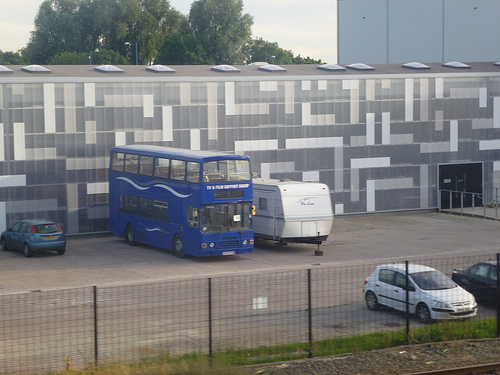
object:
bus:
[106, 143, 254, 261]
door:
[433, 161, 489, 211]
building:
[0, 2, 498, 238]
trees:
[182, 0, 254, 68]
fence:
[0, 250, 499, 370]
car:
[0, 219, 65, 258]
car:
[360, 263, 478, 324]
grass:
[255, 319, 497, 360]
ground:
[0, 205, 500, 365]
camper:
[252, 177, 334, 256]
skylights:
[143, 57, 181, 75]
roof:
[3, 68, 500, 89]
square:
[78, 83, 103, 110]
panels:
[0, 66, 494, 82]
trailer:
[272, 184, 337, 258]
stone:
[325, 112, 338, 130]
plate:
[24, 236, 66, 252]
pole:
[202, 274, 220, 353]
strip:
[162, 111, 180, 145]